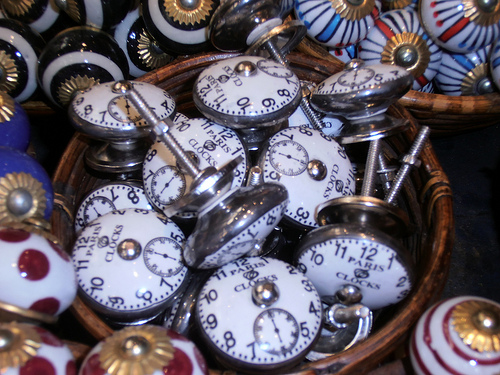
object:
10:
[204, 289, 219, 304]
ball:
[0, 150, 54, 234]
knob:
[40, 23, 129, 104]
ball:
[34, 23, 130, 107]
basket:
[45, 51, 458, 375]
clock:
[259, 127, 359, 228]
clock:
[195, 55, 301, 117]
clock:
[293, 238, 413, 311]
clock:
[307, 58, 408, 99]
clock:
[142, 115, 247, 221]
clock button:
[252, 281, 280, 305]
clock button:
[115, 240, 143, 260]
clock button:
[306, 158, 328, 180]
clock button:
[230, 61, 258, 77]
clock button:
[112, 80, 134, 94]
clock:
[70, 206, 190, 313]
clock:
[198, 255, 324, 365]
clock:
[73, 186, 157, 236]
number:
[308, 301, 319, 315]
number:
[206, 314, 218, 330]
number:
[159, 278, 174, 291]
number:
[76, 259, 89, 271]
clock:
[68, 78, 176, 136]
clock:
[197, 197, 290, 271]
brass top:
[453, 297, 500, 352]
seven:
[246, 342, 257, 361]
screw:
[125, 86, 290, 267]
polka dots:
[0, 217, 29, 242]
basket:
[275, 0, 499, 112]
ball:
[0, 230, 78, 322]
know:
[0, 226, 79, 318]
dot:
[16, 249, 50, 282]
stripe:
[43, 51, 125, 95]